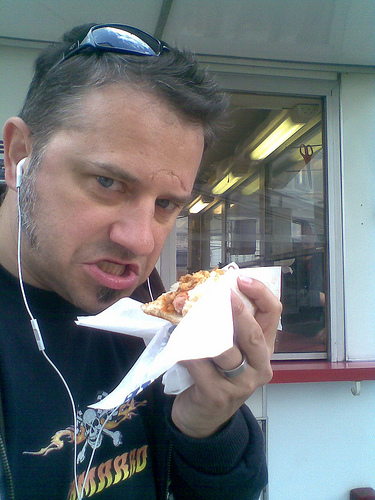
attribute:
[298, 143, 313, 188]
scissors — red, giant, suspended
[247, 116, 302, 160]
light — flourescent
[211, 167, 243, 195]
light — flourescent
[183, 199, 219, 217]
light — flourescent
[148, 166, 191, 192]
scar — weird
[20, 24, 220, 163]
hair — short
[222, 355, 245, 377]
ring — wedding ring, silver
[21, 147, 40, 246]
sideburn — grey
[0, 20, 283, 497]
man — displeased, middle aged, wearing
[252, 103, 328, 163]
light — flourscent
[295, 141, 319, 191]
scissors — red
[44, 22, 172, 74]
sunglasses — blue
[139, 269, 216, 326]
hot dog — wrapped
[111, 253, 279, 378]
paper — white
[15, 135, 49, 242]
burn — long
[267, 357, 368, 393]
counter — red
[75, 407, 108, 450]
skull — blazing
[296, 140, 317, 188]
scissors — hanging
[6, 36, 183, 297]
man — wearing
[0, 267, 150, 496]
shirt — black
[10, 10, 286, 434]
man — eating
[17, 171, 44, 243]
sideburns — graying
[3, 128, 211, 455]
man — making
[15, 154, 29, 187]
earbud — white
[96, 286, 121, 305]
beard — scruffy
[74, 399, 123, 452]
skull — white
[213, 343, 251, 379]
ring — silver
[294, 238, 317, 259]
expression — goofy 